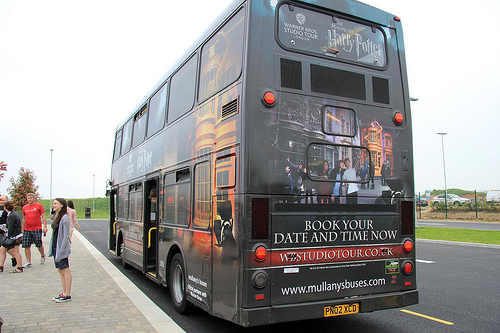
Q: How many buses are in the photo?
A: One.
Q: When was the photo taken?
A: In the daytime.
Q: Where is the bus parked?
A: By the sidewalk.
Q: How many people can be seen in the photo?
A: Five.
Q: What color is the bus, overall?
A: Black.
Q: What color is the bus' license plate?
A: Yellow.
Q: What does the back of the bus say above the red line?
A: Book your date and time now.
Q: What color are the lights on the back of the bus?
A: Red.